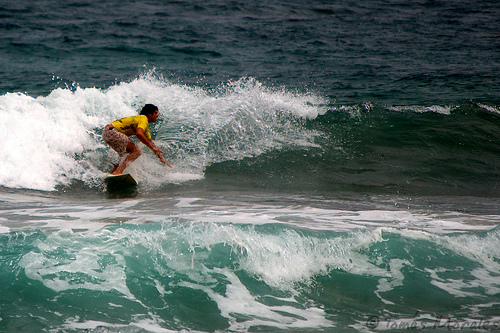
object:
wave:
[0, 64, 497, 193]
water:
[0, 0, 500, 333]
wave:
[0, 217, 499, 332]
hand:
[151, 147, 167, 154]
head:
[137, 102, 161, 124]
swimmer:
[99, 101, 173, 177]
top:
[109, 114, 153, 140]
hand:
[157, 159, 174, 169]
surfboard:
[104, 172, 141, 200]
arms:
[132, 126, 167, 155]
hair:
[140, 104, 158, 116]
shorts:
[101, 125, 141, 156]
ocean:
[0, 0, 498, 332]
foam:
[0, 65, 377, 192]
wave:
[393, 70, 493, 84]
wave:
[302, 39, 330, 47]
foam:
[384, 102, 463, 116]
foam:
[473, 99, 499, 116]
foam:
[98, 222, 390, 294]